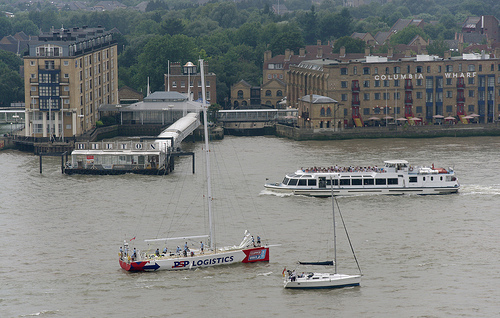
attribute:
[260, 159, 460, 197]
yacht — large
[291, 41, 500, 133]
building — warehouse, in background, columbia wharf, outer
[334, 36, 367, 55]
tree — surrounding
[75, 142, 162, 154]
sign — hilton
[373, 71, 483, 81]
sign — columbia wharf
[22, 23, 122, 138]
hotel — large, tall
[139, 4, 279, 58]
area — wooded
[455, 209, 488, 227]
wave — small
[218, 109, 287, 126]
walk way — covered, pedestrian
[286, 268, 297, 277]
shipmate — working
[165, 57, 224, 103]
building — small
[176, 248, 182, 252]
shirt — blue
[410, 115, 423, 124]
umbrella — tan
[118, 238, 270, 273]
boat — red, white, large, medium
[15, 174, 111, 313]
water — along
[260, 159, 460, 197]
boat — large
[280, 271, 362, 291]
boat — small, blue, white